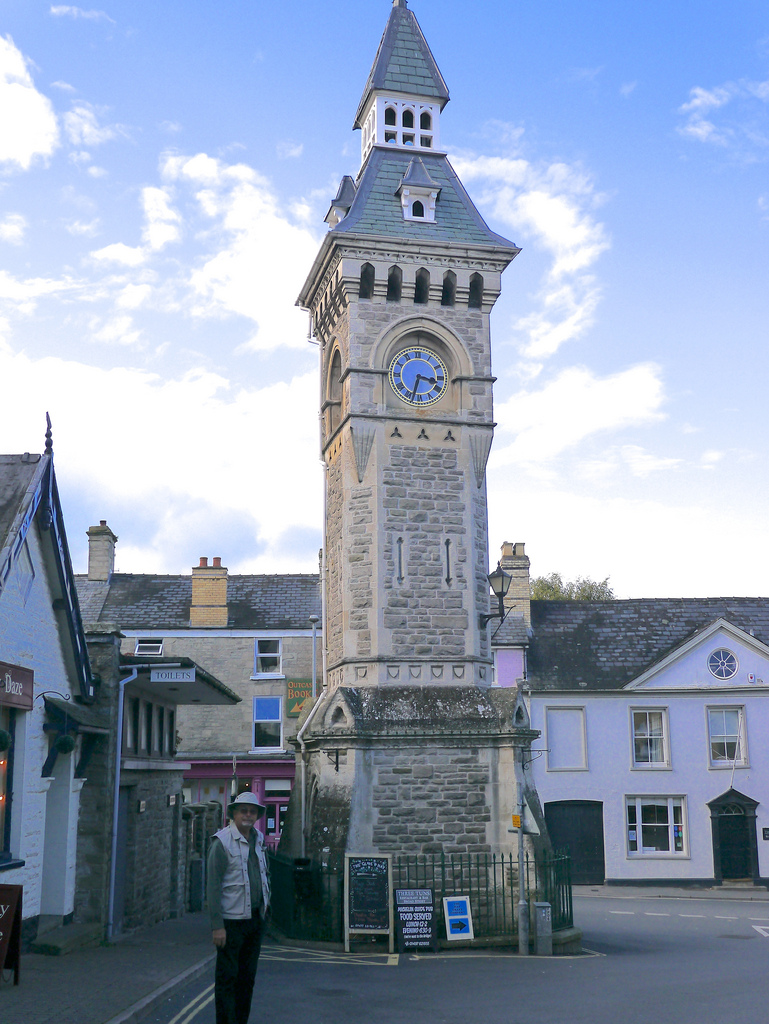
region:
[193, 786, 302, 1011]
the man standing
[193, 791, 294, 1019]
A man standing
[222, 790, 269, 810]
The tan hat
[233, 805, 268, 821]
The black sunglasses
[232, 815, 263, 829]
The beard of the man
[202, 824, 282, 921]
The tan jacket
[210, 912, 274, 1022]
The black pants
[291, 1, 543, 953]
The tower has a clock on it.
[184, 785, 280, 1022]
The man is wearing a vest.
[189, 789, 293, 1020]
The man is wearing a hat.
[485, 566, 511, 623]
The tower has a lamp turned off during the daytime.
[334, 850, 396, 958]
The sign is a chalk board.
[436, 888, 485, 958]
The sign is blue with a black arrow.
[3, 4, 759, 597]
The sky is blue with white clouds.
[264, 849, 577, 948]
The fence around the tower is green.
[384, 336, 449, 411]
blue clock on tower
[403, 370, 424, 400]
minute hand of clock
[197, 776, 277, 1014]
man in tan hat and vest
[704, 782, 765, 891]
green door on white building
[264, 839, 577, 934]
green fence around tower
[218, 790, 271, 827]
man using a hat in his head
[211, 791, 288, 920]
man whit a green sweter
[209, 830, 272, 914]
man whit sport waistcoat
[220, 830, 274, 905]
gray sport waistcoat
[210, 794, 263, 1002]
man whit a black pant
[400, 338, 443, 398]
clock on the top of tower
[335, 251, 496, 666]
gray brick tower on the street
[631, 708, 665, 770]
frontal glass window whit white frame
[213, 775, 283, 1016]
man wearing white vest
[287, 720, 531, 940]
base of the clock tower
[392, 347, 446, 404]
blue clock face on the tower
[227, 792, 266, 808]
hat the man is working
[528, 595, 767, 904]
white house with gray roof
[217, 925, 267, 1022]
black pants the man is wearing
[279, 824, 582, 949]
railing around the tower base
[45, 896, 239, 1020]
sidewalk beside the man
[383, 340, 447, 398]
roman numerals on the clock face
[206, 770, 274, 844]
the head of a grown person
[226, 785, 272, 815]
the hat of a grown person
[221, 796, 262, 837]
the face of a grown person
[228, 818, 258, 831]
the beard of a grown person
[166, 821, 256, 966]
the arm of a grown person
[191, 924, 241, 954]
the hand of a grown person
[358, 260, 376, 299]
A window on a building.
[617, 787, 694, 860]
A window on a building.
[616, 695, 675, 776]
A window on a building.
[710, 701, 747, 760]
A window on a building.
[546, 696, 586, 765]
A window on a building.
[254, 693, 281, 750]
A window on a building.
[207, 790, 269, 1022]
the man is standing up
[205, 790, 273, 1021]
the man is wearing a hat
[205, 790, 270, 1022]
the man is wearing a vest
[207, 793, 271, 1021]
the man is wearing long pants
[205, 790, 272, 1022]
the man is wearing a long sleeved shirt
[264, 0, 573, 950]
the clock on the tower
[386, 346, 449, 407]
the roman numerals on the clock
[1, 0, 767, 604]
the white clouds in the blue sky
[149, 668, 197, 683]
the sign say's TOILETS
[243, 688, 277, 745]
A window on a building.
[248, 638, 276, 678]
A window on a building.